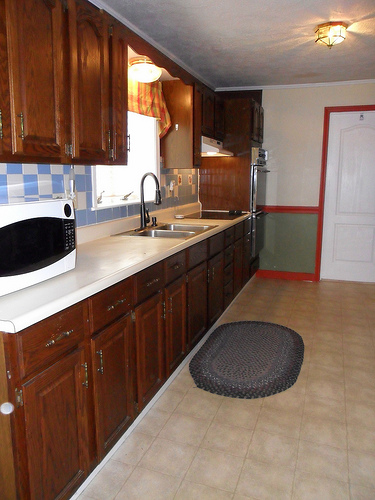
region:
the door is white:
[320, 100, 367, 284]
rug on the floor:
[211, 301, 303, 440]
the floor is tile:
[166, 445, 240, 474]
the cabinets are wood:
[33, 345, 118, 429]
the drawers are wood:
[70, 277, 146, 317]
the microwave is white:
[3, 218, 83, 283]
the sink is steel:
[141, 210, 202, 232]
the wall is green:
[280, 227, 317, 256]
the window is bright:
[116, 126, 162, 158]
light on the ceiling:
[280, 6, 368, 53]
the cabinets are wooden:
[35, 89, 271, 352]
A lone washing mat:
[199, 318, 290, 390]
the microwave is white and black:
[4, 193, 79, 280]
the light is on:
[137, 57, 162, 83]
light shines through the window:
[93, 115, 167, 219]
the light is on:
[293, 12, 354, 74]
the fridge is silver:
[244, 136, 271, 237]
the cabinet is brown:
[11, 52, 104, 128]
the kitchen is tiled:
[233, 289, 372, 494]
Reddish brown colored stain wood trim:
[264, 104, 374, 284]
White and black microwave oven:
[1, 198, 78, 295]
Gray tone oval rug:
[190, 320, 305, 400]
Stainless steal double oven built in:
[248, 146, 270, 257]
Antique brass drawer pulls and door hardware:
[44, 328, 105, 390]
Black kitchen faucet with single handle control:
[139, 171, 163, 229]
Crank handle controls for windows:
[95, 189, 135, 204]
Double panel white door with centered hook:
[321, 108, 373, 281]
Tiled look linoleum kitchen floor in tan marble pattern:
[162, 401, 373, 489]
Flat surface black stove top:
[181, 208, 247, 221]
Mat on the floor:
[181, 313, 313, 402]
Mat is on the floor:
[182, 316, 308, 400]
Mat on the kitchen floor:
[181, 317, 312, 399]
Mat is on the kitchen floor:
[184, 317, 311, 402]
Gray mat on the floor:
[176, 313, 309, 401]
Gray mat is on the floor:
[186, 315, 314, 401]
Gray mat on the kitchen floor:
[182, 318, 308, 403]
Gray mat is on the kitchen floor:
[182, 313, 306, 401]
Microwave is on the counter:
[0, 188, 90, 300]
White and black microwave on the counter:
[0, 196, 85, 300]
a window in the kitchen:
[108, 86, 155, 196]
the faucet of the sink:
[132, 168, 159, 228]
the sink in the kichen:
[139, 219, 201, 234]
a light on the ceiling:
[304, 18, 350, 48]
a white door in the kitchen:
[320, 109, 369, 275]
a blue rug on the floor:
[192, 317, 308, 396]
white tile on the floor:
[138, 405, 363, 483]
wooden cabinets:
[7, 315, 154, 496]